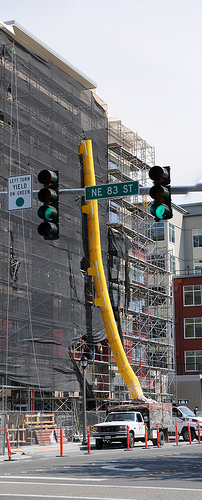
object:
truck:
[92, 409, 148, 447]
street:
[3, 439, 202, 500]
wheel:
[129, 431, 135, 449]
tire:
[159, 428, 164, 443]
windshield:
[105, 409, 135, 424]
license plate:
[105, 434, 112, 443]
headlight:
[120, 421, 126, 432]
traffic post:
[59, 425, 65, 456]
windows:
[184, 323, 194, 338]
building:
[131, 200, 202, 416]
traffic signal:
[36, 164, 60, 239]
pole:
[0, 183, 202, 204]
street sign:
[83, 178, 140, 206]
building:
[0, 18, 109, 426]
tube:
[78, 135, 144, 401]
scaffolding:
[108, 117, 178, 407]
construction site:
[0, 1, 202, 499]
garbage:
[123, 386, 170, 410]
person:
[6, 86, 15, 103]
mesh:
[0, 29, 110, 393]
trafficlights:
[148, 158, 173, 222]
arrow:
[97, 459, 149, 476]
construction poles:
[4, 425, 13, 464]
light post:
[81, 358, 88, 446]